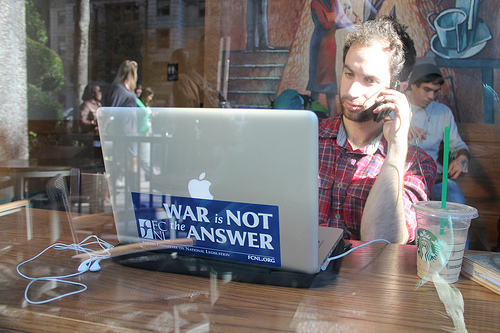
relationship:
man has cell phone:
[310, 8, 443, 240] [373, 80, 405, 118]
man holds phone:
[314, 18, 436, 245] [372, 75, 401, 124]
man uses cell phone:
[314, 18, 436, 245] [354, 81, 394, 131]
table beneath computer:
[1, 210, 461, 325] [75, 98, 340, 269]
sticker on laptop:
[130, 190, 282, 268] [95, 93, 349, 287]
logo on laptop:
[172, 169, 223, 204] [88, 100, 354, 294]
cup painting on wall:
[418, 1, 498, 68] [198, 0, 490, 222]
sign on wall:
[166, 60, 178, 81] [78, 2, 205, 209]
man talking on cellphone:
[314, 18, 436, 245] [373, 102, 388, 120]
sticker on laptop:
[127, 181, 281, 278] [95, 93, 349, 287]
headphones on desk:
[34, 241, 151, 309] [99, 254, 416, 309]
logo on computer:
[187, 172, 214, 207] [101, 99, 321, 291]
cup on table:
[407, 124, 480, 284] [1, 195, 453, 328]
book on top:
[460, 251, 499, 295] [3, 200, 453, 323]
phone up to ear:
[382, 72, 404, 120] [384, 72, 400, 94]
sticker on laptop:
[130, 190, 282, 268] [92, 98, 360, 278]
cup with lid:
[392, 122, 497, 304] [408, 190, 479, 225]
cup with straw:
[392, 122, 497, 304] [431, 114, 461, 244]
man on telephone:
[314, 18, 436, 245] [362, 69, 422, 141]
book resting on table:
[459, 248, 498, 289] [1, 203, 498, 331]